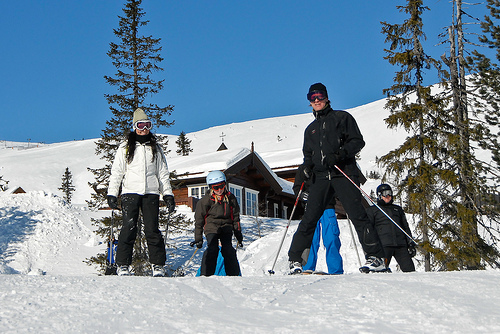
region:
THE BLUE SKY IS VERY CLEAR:
[0, 0, 498, 170]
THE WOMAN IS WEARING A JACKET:
[103, 135, 179, 197]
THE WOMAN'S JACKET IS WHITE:
[93, 133, 186, 204]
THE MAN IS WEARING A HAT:
[306, 83, 325, 104]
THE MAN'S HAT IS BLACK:
[301, 77, 332, 103]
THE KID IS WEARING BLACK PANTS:
[276, 168, 388, 270]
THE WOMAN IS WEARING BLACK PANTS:
[113, 187, 173, 270]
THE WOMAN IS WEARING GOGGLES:
[128, 118, 153, 133]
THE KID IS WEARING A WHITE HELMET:
[203, 167, 228, 191]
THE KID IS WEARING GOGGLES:
[209, 182, 226, 192]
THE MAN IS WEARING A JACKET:
[296, 99, 374, 201]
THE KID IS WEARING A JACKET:
[186, 185, 251, 251]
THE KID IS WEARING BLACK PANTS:
[199, 228, 244, 283]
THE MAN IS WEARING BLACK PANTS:
[286, 176, 383, 268]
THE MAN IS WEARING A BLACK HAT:
[300, 80, 333, 104]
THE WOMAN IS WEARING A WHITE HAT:
[131, 103, 152, 128]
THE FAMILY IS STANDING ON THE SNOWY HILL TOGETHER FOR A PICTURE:
[94, 85, 379, 277]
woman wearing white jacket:
[96, 92, 174, 284]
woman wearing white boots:
[95, 104, 185, 282]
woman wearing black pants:
[92, 91, 174, 281]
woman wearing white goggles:
[88, 95, 179, 274]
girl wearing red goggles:
[182, 148, 254, 274]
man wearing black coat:
[268, 63, 424, 282]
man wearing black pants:
[266, 69, 404, 274]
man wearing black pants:
[370, 174, 429, 281]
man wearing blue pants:
[298, 159, 343, 273]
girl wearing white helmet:
[185, 160, 254, 278]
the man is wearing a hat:
[307, 80, 327, 97]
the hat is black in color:
[307, 80, 325, 96]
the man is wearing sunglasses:
[310, 94, 327, 102]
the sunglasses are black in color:
[307, 93, 325, 103]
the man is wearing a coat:
[302, 103, 361, 206]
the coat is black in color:
[303, 106, 363, 209]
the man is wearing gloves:
[288, 155, 343, 188]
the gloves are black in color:
[287, 163, 341, 193]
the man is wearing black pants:
[290, 180, 390, 265]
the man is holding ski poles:
[270, 163, 424, 278]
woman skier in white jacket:
[107, 106, 169, 279]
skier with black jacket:
[270, 85, 384, 273]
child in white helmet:
[190, 168, 251, 279]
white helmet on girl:
[202, 171, 228, 186]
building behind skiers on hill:
[173, 154, 285, 211]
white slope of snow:
[5, 268, 493, 330]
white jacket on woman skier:
[105, 136, 180, 200]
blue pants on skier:
[310, 209, 347, 273]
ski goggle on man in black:
[308, 94, 326, 101]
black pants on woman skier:
[114, 190, 164, 268]